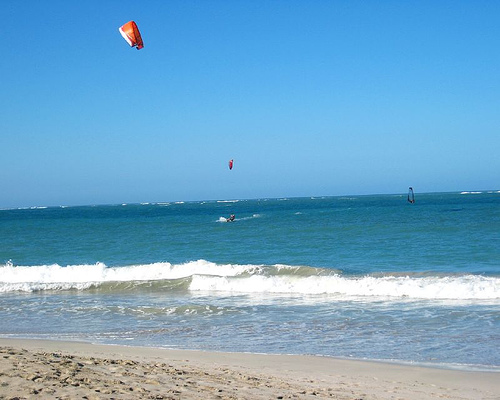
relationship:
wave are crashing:
[0, 257, 500, 311] [76, 250, 333, 316]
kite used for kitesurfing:
[112, 10, 146, 52] [224, 154, 236, 172]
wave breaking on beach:
[0, 257, 500, 311] [0, 336, 498, 397]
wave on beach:
[0, 257, 498, 307] [8, 328, 477, 398]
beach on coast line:
[1, 284, 494, 395] [32, 319, 369, 398]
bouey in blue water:
[405, 185, 415, 202] [0, 190, 500, 365]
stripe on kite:
[115, 25, 133, 45] [118, 18, 145, 50]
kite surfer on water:
[218, 206, 243, 226] [165, 232, 479, 345]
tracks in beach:
[3, 347, 497, 399] [1, 333, 500, 400]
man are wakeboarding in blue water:
[221, 210, 242, 228] [0, 190, 500, 365]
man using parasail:
[195, 191, 327, 248] [118, 16, 146, 54]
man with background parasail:
[195, 191, 327, 248] [224, 156, 238, 175]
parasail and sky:
[227, 160, 234, 169] [149, 2, 475, 139]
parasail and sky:
[118, 21, 143, 51] [149, 2, 475, 139]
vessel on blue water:
[404, 187, 415, 203] [0, 190, 500, 365]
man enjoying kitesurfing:
[221, 210, 242, 228] [115, 22, 240, 223]